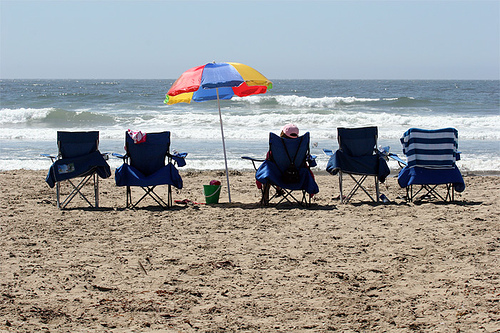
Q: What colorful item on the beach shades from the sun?
A: Umbrella.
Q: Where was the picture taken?
A: On a beach.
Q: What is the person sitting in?
A: Chair.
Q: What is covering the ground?
A: Sand.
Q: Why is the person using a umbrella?
A: For shade.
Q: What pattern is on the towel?
A: Stripes.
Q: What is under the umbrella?
A: A bucket.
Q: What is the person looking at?
A: The ocean.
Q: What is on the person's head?
A: A hat.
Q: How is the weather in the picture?
A: Sunny.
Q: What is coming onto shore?
A: Waves.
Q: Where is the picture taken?
A: A beach.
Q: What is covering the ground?
A: Sand.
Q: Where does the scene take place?
A: On the beach.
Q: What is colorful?
A: Beach umbrella.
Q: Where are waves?
A: In the ocean.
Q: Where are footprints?
A: On the sand.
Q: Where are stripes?
A: On a towel.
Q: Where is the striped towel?
A: On chair on the right.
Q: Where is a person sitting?
A: On a chair.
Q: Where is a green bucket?
A: On the sand.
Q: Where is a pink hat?
A: On person's head.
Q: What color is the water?
A: Blue.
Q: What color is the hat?
A: Pink.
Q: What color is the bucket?
A: Green.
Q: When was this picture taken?
A: During the day.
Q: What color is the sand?
A: Brown.